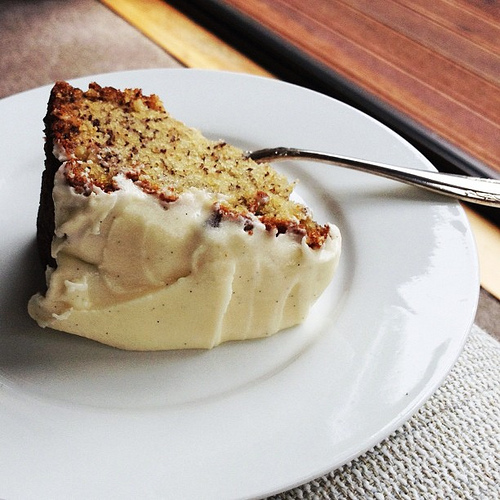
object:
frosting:
[25, 163, 344, 353]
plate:
[3, 68, 479, 499]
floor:
[305, 1, 499, 107]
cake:
[25, 79, 342, 350]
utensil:
[243, 145, 498, 207]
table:
[1, 2, 499, 346]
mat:
[257, 323, 498, 497]